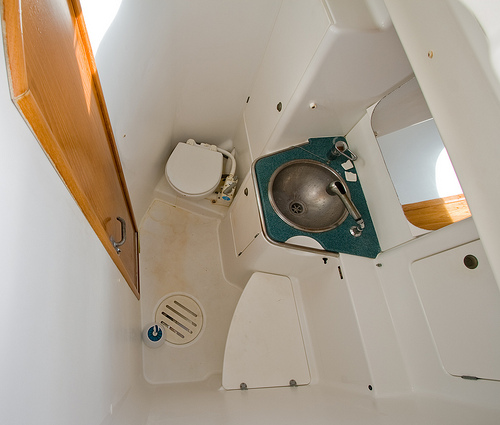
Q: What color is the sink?
A: Silver.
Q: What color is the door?
A: Brown.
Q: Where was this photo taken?
A: In a bathroom.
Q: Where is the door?
A: On the left.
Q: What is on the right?
A: The sink.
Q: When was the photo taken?
A: Daytime.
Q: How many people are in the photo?
A: None.